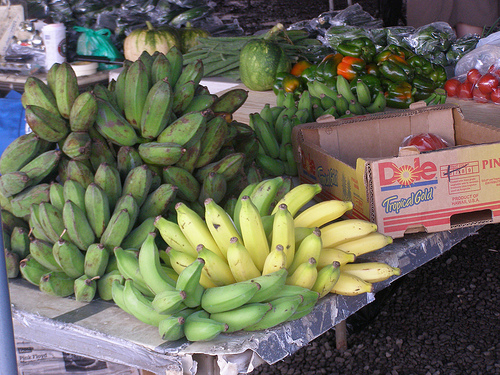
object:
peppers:
[335, 50, 378, 79]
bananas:
[330, 76, 358, 104]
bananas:
[173, 199, 210, 256]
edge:
[13, 310, 182, 372]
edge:
[252, 310, 322, 361]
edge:
[416, 227, 492, 257]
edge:
[373, 253, 411, 287]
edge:
[303, 308, 345, 335]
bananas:
[137, 79, 175, 137]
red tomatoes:
[442, 76, 463, 97]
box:
[294, 101, 500, 240]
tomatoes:
[490, 91, 500, 106]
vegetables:
[207, 35, 245, 54]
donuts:
[455, 43, 499, 80]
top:
[96, 308, 156, 335]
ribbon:
[76, 21, 111, 40]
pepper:
[396, 127, 459, 161]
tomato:
[476, 72, 499, 93]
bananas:
[20, 74, 69, 143]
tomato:
[466, 68, 482, 85]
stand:
[0, 228, 486, 373]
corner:
[160, 348, 272, 373]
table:
[12, 79, 495, 373]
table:
[0, 67, 125, 90]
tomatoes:
[488, 63, 500, 76]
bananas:
[138, 227, 176, 297]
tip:
[248, 278, 265, 295]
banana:
[295, 200, 354, 227]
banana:
[200, 280, 261, 312]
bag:
[458, 41, 498, 76]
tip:
[277, 198, 294, 220]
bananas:
[158, 106, 208, 162]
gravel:
[433, 333, 495, 371]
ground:
[393, 275, 495, 364]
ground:
[303, 343, 494, 370]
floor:
[363, 297, 498, 359]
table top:
[9, 277, 75, 352]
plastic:
[75, 36, 122, 62]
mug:
[41, 21, 66, 72]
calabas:
[122, 11, 177, 62]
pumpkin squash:
[179, 22, 217, 51]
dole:
[378, 156, 438, 188]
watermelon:
[238, 39, 290, 90]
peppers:
[404, 70, 443, 97]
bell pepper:
[374, 51, 417, 81]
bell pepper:
[338, 30, 377, 59]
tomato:
[456, 83, 474, 101]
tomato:
[470, 85, 492, 103]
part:
[58, 303, 114, 328]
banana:
[267, 203, 292, 265]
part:
[308, 209, 321, 218]